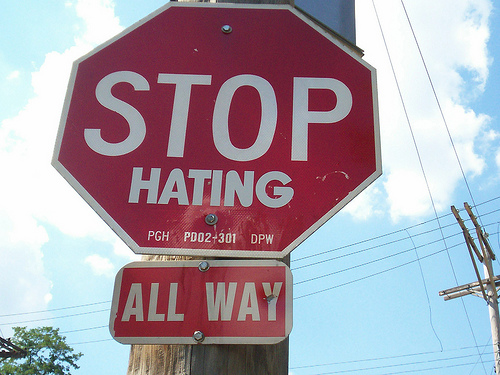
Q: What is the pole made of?
A: Wood.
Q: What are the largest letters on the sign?
A: STOP.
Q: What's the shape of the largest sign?
A: Octagon.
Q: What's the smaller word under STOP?
A: HATING.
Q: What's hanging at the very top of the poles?
A: Power lines.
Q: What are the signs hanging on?
A: The pole.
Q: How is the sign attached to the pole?
A: Bolts.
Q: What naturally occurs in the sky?
A: Clouds.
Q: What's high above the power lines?
A: Clouds.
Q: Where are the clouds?
A: In the sky.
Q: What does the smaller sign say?
A: ALL WAY.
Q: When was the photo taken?
A: During the daytime.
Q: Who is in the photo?
A: No people.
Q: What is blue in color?
A: The sky.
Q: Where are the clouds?
A: In the sky.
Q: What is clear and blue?
A: The sky.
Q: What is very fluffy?
A: The clouds.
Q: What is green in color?
A: The tree.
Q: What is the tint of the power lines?
A: Black.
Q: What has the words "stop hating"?
A: A sign.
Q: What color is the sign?
A: Red.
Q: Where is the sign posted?
A: A telephone pole.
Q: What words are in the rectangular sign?
A: All Way.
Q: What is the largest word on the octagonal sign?
A: Stop.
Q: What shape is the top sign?
A: An octagon.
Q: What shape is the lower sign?
A: A rectangle.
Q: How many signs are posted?
A: Two.